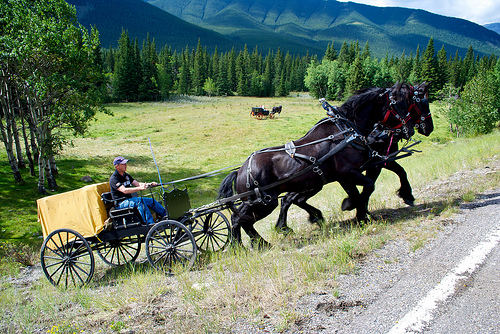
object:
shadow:
[290, 191, 499, 250]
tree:
[111, 27, 143, 105]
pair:
[221, 76, 436, 257]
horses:
[274, 79, 433, 240]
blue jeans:
[117, 194, 166, 224]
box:
[34, 181, 111, 254]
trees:
[200, 76, 217, 98]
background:
[0, 0, 499, 333]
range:
[144, 0, 499, 68]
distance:
[330, 0, 498, 33]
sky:
[335, 0, 499, 25]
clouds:
[334, 0, 499, 27]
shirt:
[109, 170, 135, 201]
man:
[107, 157, 166, 224]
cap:
[110, 155, 132, 165]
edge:
[341, 176, 499, 334]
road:
[335, 188, 499, 333]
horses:
[219, 74, 416, 257]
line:
[387, 228, 499, 334]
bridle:
[147, 165, 241, 188]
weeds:
[181, 294, 209, 317]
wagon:
[34, 167, 277, 292]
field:
[0, 92, 498, 334]